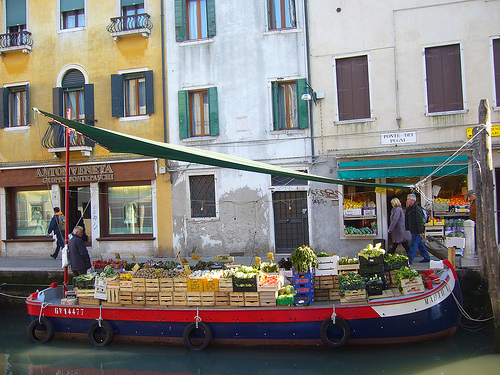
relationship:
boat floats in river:
[24, 249, 471, 357] [0, 309, 497, 374]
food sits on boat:
[93, 266, 389, 302] [24, 249, 471, 357]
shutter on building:
[111, 71, 126, 118] [1, 2, 173, 271]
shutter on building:
[145, 70, 153, 113] [1, 2, 173, 271]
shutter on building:
[20, 82, 28, 123] [1, 2, 173, 271]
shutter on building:
[1, 84, 9, 125] [1, 2, 173, 271]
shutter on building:
[85, 82, 92, 126] [1, 2, 173, 271]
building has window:
[158, 4, 325, 274] [294, 78, 312, 129]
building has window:
[158, 4, 325, 274] [190, 90, 202, 135]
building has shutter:
[158, 4, 325, 274] [264, 0, 295, 30]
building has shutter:
[158, 4, 325, 274] [175, 0, 217, 44]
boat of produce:
[24, 244, 464, 352] [276, 284, 293, 299]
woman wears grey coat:
[384, 195, 411, 265] [385, 205, 409, 242]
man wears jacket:
[405, 194, 432, 266] [405, 202, 425, 232]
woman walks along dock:
[384, 195, 411, 265] [407, 251, 481, 269]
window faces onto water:
[30, 65, 144, 191] [15, 345, 78, 368]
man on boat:
[64, 225, 93, 279] [22, 247, 463, 347]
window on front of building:
[161, 90, 215, 145] [164, 5, 324, 254]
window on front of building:
[265, 74, 312, 134] [164, 5, 324, 254]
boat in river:
[24, 244, 464, 352] [3, 305, 498, 372]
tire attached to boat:
[174, 314, 217, 351] [24, 249, 471, 357]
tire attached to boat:
[320, 315, 350, 347] [31, 265, 467, 349]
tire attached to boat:
[180, 319, 213, 353] [31, 265, 467, 349]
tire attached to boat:
[88, 317, 115, 345] [31, 265, 467, 349]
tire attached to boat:
[27, 319, 56, 339] [31, 265, 467, 349]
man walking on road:
[402, 192, 431, 264] [0, 255, 499, 273]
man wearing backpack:
[46, 206, 66, 257] [58, 214, 68, 234]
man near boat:
[59, 222, 99, 280] [18, 231, 468, 350]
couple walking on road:
[386, 194, 431, 264] [0, 255, 499, 273]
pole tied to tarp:
[476, 100, 498, 327] [26, 100, 426, 200]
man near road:
[46, 206, 66, 260] [6, 255, 61, 270]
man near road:
[64, 225, 93, 279] [6, 255, 61, 270]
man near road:
[402, 192, 431, 264] [6, 255, 61, 270]